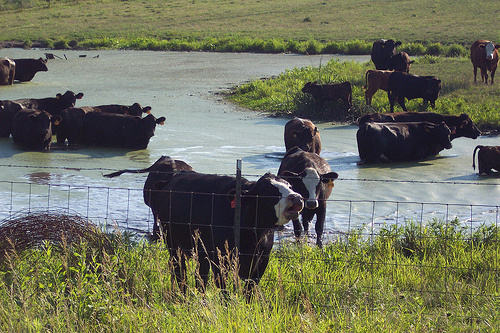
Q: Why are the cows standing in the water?
A: They are taking a bath.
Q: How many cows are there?
A: Sixteen.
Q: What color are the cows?
A: Black, brown and white.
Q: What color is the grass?
A: Green.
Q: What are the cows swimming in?
A: Water.